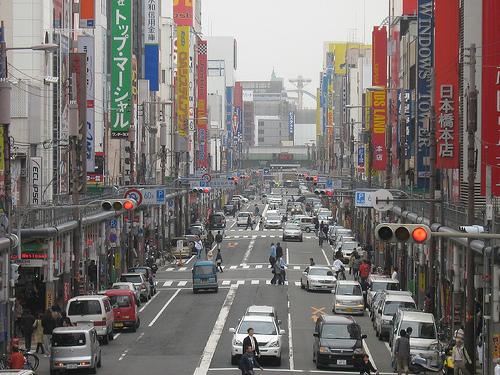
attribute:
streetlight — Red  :
[409, 223, 429, 245]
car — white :
[184, 291, 329, 362]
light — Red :
[377, 216, 494, 251]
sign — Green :
[90, 0, 155, 152]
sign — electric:
[10, 250, 56, 261]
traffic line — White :
[196, 277, 238, 374]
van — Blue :
[180, 255, 224, 297]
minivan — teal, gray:
[192, 261, 224, 293]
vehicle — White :
[228, 315, 287, 363]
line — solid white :
[203, 325, 223, 359]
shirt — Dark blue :
[267, 245, 277, 261]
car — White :
[235, 315, 285, 356]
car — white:
[230, 315, 281, 359]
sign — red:
[431, 1, 463, 165]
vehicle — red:
[101, 287, 141, 331]